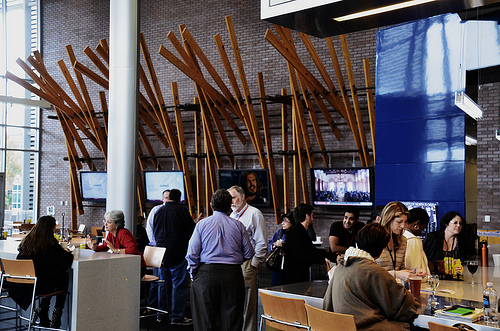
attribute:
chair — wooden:
[260, 291, 308, 330]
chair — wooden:
[305, 303, 358, 330]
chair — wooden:
[0, 257, 71, 330]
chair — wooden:
[139, 245, 168, 323]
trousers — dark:
[191, 260, 243, 329]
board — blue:
[376, 13, 477, 221]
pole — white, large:
[107, 2, 139, 239]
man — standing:
[184, 190, 256, 330]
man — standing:
[152, 188, 196, 326]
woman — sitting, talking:
[19, 238, 74, 294]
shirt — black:
[17, 242, 73, 292]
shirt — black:
[153, 202, 194, 268]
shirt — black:
[279, 222, 336, 283]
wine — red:
[467, 260, 478, 287]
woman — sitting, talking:
[85, 210, 147, 278]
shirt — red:
[95, 230, 145, 268]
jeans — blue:
[156, 262, 187, 318]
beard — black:
[308, 215, 314, 228]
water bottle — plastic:
[483, 281, 497, 324]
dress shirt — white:
[228, 204, 268, 268]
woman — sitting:
[319, 221, 422, 329]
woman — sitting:
[374, 201, 409, 272]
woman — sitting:
[422, 212, 466, 264]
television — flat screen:
[215, 170, 272, 211]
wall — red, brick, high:
[39, 0, 376, 253]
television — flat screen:
[80, 170, 109, 200]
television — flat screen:
[144, 171, 189, 207]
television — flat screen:
[309, 166, 374, 211]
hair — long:
[16, 216, 59, 262]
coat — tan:
[322, 256, 420, 330]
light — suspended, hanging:
[454, 7, 483, 119]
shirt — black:
[328, 222, 367, 261]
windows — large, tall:
[1, 1, 40, 231]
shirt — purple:
[183, 212, 255, 265]